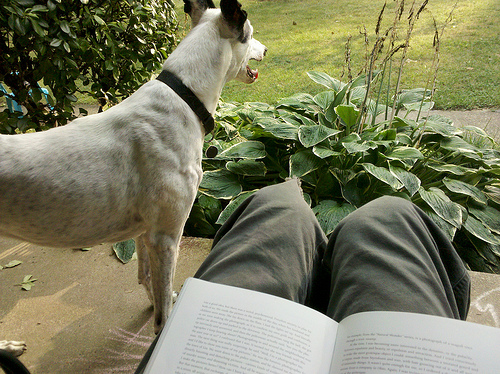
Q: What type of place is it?
A: It is a porch.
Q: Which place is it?
A: It is a porch.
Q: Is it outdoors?
A: Yes, it is outdoors.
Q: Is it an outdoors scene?
A: Yes, it is outdoors.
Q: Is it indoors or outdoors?
A: It is outdoors.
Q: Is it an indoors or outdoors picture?
A: It is outdoors.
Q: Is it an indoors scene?
A: No, it is outdoors.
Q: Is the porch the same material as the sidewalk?
A: Yes, both the porch and the sidewalk are made of cement.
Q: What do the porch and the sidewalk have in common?
A: The material, both the porch and the sidewalk are concrete.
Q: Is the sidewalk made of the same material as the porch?
A: Yes, both the sidewalk and the porch are made of concrete.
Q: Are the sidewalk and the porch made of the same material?
A: Yes, both the sidewalk and the porch are made of concrete.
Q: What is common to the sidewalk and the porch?
A: The material, both the sidewalk and the porch are concrete.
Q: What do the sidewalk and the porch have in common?
A: The material, both the sidewalk and the porch are concrete.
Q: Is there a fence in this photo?
A: No, there are no fences.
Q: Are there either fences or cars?
A: No, there are no fences or cars.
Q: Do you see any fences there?
A: No, there are no fences.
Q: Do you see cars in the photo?
A: No, there are no cars.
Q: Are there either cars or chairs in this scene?
A: No, there are no cars or chairs.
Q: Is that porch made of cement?
A: Yes, the porch is made of cement.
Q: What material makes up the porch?
A: The porch is made of cement.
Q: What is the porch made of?
A: The porch is made of concrete.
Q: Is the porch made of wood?
A: No, the porch is made of cement.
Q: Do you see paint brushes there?
A: No, there are no paint brushes.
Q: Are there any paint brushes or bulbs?
A: No, there are no paint brushes or bulbs.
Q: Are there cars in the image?
A: No, there are no cars.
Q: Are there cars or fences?
A: No, there are no cars or fences.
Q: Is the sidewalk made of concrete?
A: Yes, the sidewalk is made of concrete.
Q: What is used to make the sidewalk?
A: The sidewalk is made of cement.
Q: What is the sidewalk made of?
A: The sidewalk is made of concrete.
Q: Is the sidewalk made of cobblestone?
A: No, the sidewalk is made of cement.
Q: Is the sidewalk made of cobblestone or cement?
A: The sidewalk is made of cement.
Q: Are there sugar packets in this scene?
A: No, there are no sugar packets.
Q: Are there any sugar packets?
A: No, there are no sugar packets.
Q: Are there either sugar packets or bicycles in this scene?
A: No, there are no sugar packets or bicycles.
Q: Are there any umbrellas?
A: No, there are no umbrellas.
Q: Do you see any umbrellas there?
A: No, there are no umbrellas.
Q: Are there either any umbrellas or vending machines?
A: No, there are no umbrellas or vending machines.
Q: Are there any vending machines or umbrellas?
A: No, there are no umbrellas or vending machines.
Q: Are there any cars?
A: No, there are no cars.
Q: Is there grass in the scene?
A: Yes, there is grass.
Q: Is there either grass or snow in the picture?
A: Yes, there is grass.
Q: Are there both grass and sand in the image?
A: No, there is grass but no sand.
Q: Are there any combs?
A: No, there are no combs.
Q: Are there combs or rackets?
A: No, there are no combs or rackets.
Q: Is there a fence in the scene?
A: No, there are no fences.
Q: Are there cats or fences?
A: No, there are no fences or cats.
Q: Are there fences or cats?
A: No, there are no fences or cats.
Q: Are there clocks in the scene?
A: No, there are no clocks.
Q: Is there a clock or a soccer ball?
A: No, there are no clocks or soccer balls.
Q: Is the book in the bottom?
A: Yes, the book is in the bottom of the image.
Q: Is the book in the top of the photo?
A: No, the book is in the bottom of the image.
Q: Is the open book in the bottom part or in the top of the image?
A: The book is in the bottom of the image.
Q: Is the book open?
A: Yes, the book is open.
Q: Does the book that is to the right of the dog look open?
A: Yes, the book is open.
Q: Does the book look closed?
A: No, the book is open.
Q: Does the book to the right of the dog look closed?
A: No, the book is open.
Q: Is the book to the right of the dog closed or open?
A: The book is open.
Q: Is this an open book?
A: Yes, this is an open book.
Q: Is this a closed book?
A: No, this is an open book.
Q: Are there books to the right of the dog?
A: Yes, there is a book to the right of the dog.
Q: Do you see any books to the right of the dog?
A: Yes, there is a book to the right of the dog.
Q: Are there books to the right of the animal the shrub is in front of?
A: Yes, there is a book to the right of the dog.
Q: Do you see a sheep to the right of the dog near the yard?
A: No, there is a book to the right of the dog.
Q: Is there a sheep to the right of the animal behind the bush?
A: No, there is a book to the right of the dog.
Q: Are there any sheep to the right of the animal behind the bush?
A: No, there is a book to the right of the dog.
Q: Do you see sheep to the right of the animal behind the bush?
A: No, there is a book to the right of the dog.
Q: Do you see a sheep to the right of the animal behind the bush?
A: No, there is a book to the right of the dog.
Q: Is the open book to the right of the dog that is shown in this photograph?
A: Yes, the book is to the right of the dog.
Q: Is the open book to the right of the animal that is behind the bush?
A: Yes, the book is to the right of the dog.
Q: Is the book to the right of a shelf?
A: No, the book is to the right of the dog.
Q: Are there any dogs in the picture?
A: Yes, there is a dog.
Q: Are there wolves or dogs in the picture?
A: Yes, there is a dog.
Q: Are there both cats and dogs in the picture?
A: No, there is a dog but no cats.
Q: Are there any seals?
A: No, there are no seals.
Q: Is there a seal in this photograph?
A: No, there are no seals.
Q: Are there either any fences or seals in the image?
A: No, there are no seals or fences.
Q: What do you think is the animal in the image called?
A: The animal is a dog.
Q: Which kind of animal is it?
A: The animal is a dog.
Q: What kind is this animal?
A: This is a dog.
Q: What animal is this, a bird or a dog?
A: This is a dog.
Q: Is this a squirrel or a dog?
A: This is a dog.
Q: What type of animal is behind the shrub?
A: The animal is a dog.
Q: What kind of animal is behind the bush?
A: The animal is a dog.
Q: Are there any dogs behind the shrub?
A: Yes, there is a dog behind the shrub.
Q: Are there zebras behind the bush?
A: No, there is a dog behind the bush.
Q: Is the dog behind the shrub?
A: Yes, the dog is behind the shrub.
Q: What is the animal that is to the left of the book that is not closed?
A: The animal is a dog.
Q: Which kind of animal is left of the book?
A: The animal is a dog.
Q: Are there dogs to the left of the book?
A: Yes, there is a dog to the left of the book.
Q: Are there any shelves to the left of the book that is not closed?
A: No, there is a dog to the left of the book.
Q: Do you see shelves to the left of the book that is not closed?
A: No, there is a dog to the left of the book.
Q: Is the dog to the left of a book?
A: Yes, the dog is to the left of a book.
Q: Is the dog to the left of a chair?
A: No, the dog is to the left of a book.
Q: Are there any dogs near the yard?
A: Yes, there is a dog near the yard.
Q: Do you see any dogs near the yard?
A: Yes, there is a dog near the yard.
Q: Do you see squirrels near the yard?
A: No, there is a dog near the yard.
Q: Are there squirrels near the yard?
A: No, there is a dog near the yard.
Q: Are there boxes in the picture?
A: No, there are no boxes.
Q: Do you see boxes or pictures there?
A: No, there are no boxes or pictures.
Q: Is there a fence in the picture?
A: No, there are no fences.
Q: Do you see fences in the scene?
A: No, there are no fences.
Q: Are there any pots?
A: No, there are no pots.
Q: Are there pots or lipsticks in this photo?
A: No, there are no pots or lipsticks.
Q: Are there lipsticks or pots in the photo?
A: No, there are no pots or lipsticks.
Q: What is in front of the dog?
A: The bush is in front of the dog.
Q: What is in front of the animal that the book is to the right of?
A: The bush is in front of the dog.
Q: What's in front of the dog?
A: The bush is in front of the dog.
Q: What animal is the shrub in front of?
A: The shrub is in front of the dog.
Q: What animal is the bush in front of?
A: The shrub is in front of the dog.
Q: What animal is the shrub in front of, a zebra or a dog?
A: The shrub is in front of a dog.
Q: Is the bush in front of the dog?
A: Yes, the bush is in front of the dog.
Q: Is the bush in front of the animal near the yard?
A: Yes, the bush is in front of the dog.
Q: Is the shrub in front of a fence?
A: No, the shrub is in front of the dog.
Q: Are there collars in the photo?
A: Yes, there is a collar.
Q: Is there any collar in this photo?
A: Yes, there is a collar.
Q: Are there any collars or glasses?
A: Yes, there is a collar.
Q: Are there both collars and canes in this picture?
A: No, there is a collar but no canes.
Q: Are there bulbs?
A: No, there are no bulbs.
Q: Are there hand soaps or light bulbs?
A: No, there are no light bulbs or hand soaps.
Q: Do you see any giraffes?
A: No, there are no giraffes.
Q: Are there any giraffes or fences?
A: No, there are no giraffes or fences.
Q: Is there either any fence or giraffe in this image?
A: No, there are no giraffes or fences.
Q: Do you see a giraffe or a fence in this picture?
A: No, there are no giraffes or fences.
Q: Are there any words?
A: Yes, there are words.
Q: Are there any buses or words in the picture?
A: Yes, there are words.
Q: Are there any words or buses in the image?
A: Yes, there are words.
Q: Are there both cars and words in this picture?
A: No, there are words but no cars.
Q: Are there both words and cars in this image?
A: No, there are words but no cars.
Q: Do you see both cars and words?
A: No, there are words but no cars.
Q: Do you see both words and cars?
A: No, there are words but no cars.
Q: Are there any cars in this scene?
A: No, there are no cars.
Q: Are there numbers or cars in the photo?
A: No, there are no cars or numbers.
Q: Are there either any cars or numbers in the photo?
A: No, there are no cars or numbers.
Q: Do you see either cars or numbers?
A: No, there are no cars or numbers.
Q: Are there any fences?
A: No, there are no fences.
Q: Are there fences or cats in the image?
A: No, there are no fences or cats.